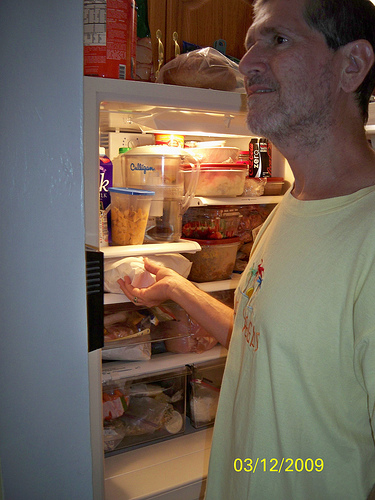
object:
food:
[97, 118, 293, 458]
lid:
[108, 185, 154, 197]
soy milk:
[98, 146, 115, 248]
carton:
[97, 152, 114, 248]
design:
[230, 253, 270, 351]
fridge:
[77, 60, 301, 497]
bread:
[155, 46, 242, 90]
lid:
[184, 233, 255, 246]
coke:
[248, 136, 272, 198]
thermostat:
[122, 136, 140, 148]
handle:
[155, 27, 163, 81]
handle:
[172, 31, 180, 57]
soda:
[248, 138, 272, 180]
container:
[121, 144, 199, 244]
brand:
[126, 157, 159, 173]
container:
[109, 186, 155, 246]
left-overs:
[110, 205, 150, 246]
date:
[226, 450, 327, 476]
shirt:
[205, 156, 375, 499]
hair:
[246, 70, 347, 162]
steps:
[99, 144, 115, 242]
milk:
[123, 146, 165, 217]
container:
[82, 0, 143, 78]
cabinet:
[0, 0, 299, 500]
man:
[203, 1, 373, 495]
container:
[180, 234, 244, 281]